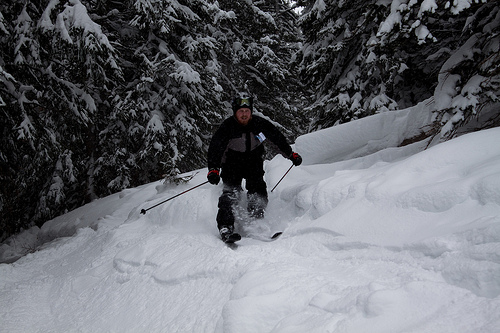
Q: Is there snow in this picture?
A: Yes, there is snow.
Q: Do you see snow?
A: Yes, there is snow.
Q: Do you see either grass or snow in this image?
A: Yes, there is snow.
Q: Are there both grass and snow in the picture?
A: No, there is snow but no grass.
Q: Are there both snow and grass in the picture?
A: No, there is snow but no grass.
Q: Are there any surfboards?
A: No, there are no surfboards.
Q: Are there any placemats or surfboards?
A: No, there are no surfboards or placemats.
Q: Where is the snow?
A: The snow is on the ground.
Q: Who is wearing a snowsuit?
A: The man is wearing a snowsuit.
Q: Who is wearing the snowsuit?
A: The man is wearing a snowsuit.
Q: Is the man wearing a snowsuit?
A: Yes, the man is wearing a snowsuit.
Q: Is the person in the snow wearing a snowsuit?
A: Yes, the man is wearing a snowsuit.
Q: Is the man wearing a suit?
A: No, the man is wearing a snowsuit.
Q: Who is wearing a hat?
A: The man is wearing a hat.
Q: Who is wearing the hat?
A: The man is wearing a hat.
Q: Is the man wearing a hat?
A: Yes, the man is wearing a hat.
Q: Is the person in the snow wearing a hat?
A: Yes, the man is wearing a hat.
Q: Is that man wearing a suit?
A: No, the man is wearing a hat.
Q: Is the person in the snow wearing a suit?
A: No, the man is wearing a hat.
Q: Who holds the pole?
A: The man holds the pole.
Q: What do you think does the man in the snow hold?
A: The man holds the pole.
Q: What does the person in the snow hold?
A: The man holds the pole.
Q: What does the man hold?
A: The man holds the pole.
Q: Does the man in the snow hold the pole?
A: Yes, the man holds the pole.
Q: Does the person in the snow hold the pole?
A: Yes, the man holds the pole.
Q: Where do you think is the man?
A: The man is in the snow.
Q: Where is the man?
A: The man is in the snow.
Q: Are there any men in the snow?
A: Yes, there is a man in the snow.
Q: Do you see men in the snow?
A: Yes, there is a man in the snow.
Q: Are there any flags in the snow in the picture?
A: No, there is a man in the snow.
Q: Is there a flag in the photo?
A: No, there are no flags.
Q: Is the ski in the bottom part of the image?
A: Yes, the ski is in the bottom of the image.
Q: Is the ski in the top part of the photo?
A: No, the ski is in the bottom of the image.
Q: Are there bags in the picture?
A: No, there are no bags.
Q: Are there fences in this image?
A: No, there are no fences.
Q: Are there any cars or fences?
A: No, there are no fences or cars.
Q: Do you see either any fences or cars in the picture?
A: No, there are no fences or cars.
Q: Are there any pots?
A: No, there are no pots.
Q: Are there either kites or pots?
A: No, there are no pots or kites.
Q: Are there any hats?
A: Yes, there is a hat.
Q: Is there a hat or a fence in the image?
A: Yes, there is a hat.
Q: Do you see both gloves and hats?
A: Yes, there are both a hat and gloves.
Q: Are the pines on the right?
A: Yes, the pines are on the right of the image.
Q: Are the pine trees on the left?
A: No, the pine trees are on the right of the image.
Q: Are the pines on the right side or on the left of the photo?
A: The pines are on the right of the image.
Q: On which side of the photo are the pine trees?
A: The pine trees are on the right of the image.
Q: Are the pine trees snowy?
A: Yes, the pine trees are snowy.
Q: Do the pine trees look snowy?
A: Yes, the pine trees are snowy.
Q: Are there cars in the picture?
A: No, there are no cars.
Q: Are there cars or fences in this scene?
A: No, there are no cars or fences.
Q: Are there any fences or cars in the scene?
A: No, there are no cars or fences.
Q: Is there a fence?
A: No, there are no fences.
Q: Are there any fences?
A: No, there are no fences.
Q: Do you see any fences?
A: No, there are no fences.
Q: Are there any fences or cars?
A: No, there are no fences or cars.